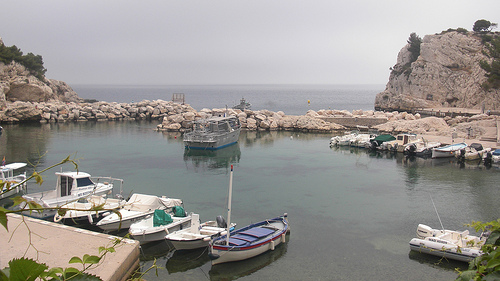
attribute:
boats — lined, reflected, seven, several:
[1, 160, 291, 267]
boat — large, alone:
[184, 113, 243, 156]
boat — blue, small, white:
[209, 214, 289, 265]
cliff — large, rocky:
[377, 30, 498, 116]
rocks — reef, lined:
[2, 99, 421, 157]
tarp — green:
[154, 205, 187, 227]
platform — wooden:
[1, 212, 143, 280]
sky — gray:
[3, 1, 498, 84]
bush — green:
[1, 39, 47, 85]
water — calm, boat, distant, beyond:
[3, 122, 499, 280]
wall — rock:
[1, 60, 78, 123]